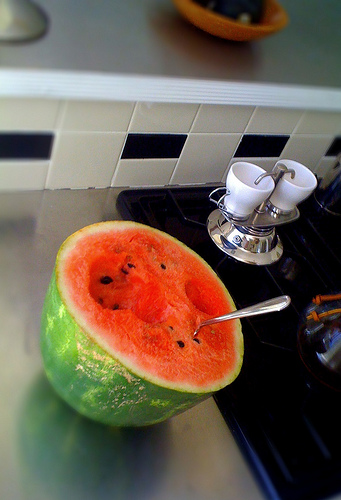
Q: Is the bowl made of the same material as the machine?
A: No, the bowl is made of wood and the machine is made of metal.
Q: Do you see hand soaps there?
A: No, there are no hand soaps.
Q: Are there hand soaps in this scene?
A: No, there are no hand soaps.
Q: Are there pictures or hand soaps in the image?
A: No, there are no hand soaps or pictures.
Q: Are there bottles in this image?
A: No, there are no bottles.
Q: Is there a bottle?
A: No, there are no bottles.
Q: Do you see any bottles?
A: No, there are no bottles.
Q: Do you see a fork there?
A: Yes, there is a fork.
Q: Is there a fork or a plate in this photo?
A: Yes, there is a fork.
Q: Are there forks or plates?
A: Yes, there is a fork.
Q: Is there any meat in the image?
A: No, there is no meat.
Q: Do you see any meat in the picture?
A: No, there is no meat.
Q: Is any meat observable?
A: No, there is no meat.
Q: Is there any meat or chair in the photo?
A: No, there are no meat or chairs.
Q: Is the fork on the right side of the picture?
A: Yes, the fork is on the right of the image.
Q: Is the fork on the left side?
A: No, the fork is on the right of the image.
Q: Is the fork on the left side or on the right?
A: The fork is on the right of the image.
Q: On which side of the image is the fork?
A: The fork is on the right of the image.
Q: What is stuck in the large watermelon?
A: The fork is stuck in the watermelon.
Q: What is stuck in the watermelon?
A: The fork is stuck in the watermelon.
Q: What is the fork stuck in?
A: The fork is stuck in the watermelon.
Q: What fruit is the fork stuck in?
A: The fork is stuck in the watermelon.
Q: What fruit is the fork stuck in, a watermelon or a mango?
A: The fork is stuck in a watermelon.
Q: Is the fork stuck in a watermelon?
A: Yes, the fork is stuck in a watermelon.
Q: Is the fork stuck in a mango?
A: No, the fork is stuck in a watermelon.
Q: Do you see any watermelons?
A: Yes, there is a watermelon.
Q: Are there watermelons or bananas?
A: Yes, there is a watermelon.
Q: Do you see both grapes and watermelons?
A: No, there is a watermelon but no grapes.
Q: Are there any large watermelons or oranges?
A: Yes, there is a large watermelon.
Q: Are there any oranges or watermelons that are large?
A: Yes, the watermelon is large.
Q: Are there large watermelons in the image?
A: Yes, there is a large watermelon.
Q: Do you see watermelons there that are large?
A: Yes, there is a watermelon that is large.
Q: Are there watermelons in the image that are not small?
A: Yes, there is a large watermelon.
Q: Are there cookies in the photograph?
A: No, there are no cookies.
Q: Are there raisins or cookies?
A: No, there are no cookies or raisins.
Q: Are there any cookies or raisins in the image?
A: No, there are no cookies or raisins.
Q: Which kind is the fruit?
A: The fruit is a watermelon.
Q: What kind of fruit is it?
A: The fruit is a watermelon.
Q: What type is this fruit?
A: This is a watermelon.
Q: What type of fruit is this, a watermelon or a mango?
A: This is a watermelon.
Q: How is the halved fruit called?
A: The fruit is a watermelon.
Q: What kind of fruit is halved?
A: The fruit is a watermelon.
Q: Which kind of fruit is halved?
A: The fruit is a watermelon.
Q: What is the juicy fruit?
A: The fruit is a watermelon.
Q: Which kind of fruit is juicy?
A: The fruit is a watermelon.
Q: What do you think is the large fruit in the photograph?
A: The fruit is a watermelon.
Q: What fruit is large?
A: The fruit is a watermelon.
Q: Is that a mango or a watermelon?
A: That is a watermelon.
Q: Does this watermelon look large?
A: Yes, the watermelon is large.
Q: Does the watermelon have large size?
A: Yes, the watermelon is large.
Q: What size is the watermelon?
A: The watermelon is large.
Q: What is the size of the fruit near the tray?
A: The watermelon is large.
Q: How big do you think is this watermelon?
A: The watermelon is large.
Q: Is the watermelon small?
A: No, the watermelon is large.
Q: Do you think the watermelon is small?
A: No, the watermelon is large.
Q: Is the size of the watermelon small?
A: No, the watermelon is large.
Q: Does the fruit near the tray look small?
A: No, the watermelon is large.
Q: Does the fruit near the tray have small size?
A: No, the watermelon is large.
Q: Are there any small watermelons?
A: No, there is a watermelon but it is large.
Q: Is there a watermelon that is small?
A: No, there is a watermelon but it is large.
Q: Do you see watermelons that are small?
A: No, there is a watermelon but it is large.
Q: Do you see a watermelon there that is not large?
A: No, there is a watermelon but it is large.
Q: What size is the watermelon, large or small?
A: The watermelon is large.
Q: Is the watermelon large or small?
A: The watermelon is large.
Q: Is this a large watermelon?
A: Yes, this is a large watermelon.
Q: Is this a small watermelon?
A: No, this is a large watermelon.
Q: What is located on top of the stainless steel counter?
A: The watermelon is on top of the counter.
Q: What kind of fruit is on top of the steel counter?
A: The fruit is a watermelon.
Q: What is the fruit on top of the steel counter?
A: The fruit is a watermelon.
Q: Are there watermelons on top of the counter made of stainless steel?
A: Yes, there is a watermelon on top of the counter.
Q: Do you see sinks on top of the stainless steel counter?
A: No, there is a watermelon on top of the counter.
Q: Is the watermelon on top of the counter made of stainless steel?
A: Yes, the watermelon is on top of the counter.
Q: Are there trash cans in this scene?
A: No, there are no trash cans.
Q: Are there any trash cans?
A: No, there are no trash cans.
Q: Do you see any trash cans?
A: No, there are no trash cans.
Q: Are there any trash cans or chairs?
A: No, there are no trash cans or chairs.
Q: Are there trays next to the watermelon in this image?
A: Yes, there is a tray next to the watermelon.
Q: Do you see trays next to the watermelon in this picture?
A: Yes, there is a tray next to the watermelon.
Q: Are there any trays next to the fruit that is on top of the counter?
A: Yes, there is a tray next to the watermelon.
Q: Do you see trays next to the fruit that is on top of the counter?
A: Yes, there is a tray next to the watermelon.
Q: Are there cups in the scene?
A: Yes, there is a cup.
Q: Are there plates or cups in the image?
A: Yes, there is a cup.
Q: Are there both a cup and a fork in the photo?
A: Yes, there are both a cup and a fork.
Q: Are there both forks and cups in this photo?
A: Yes, there are both a cup and a fork.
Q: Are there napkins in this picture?
A: No, there are no napkins.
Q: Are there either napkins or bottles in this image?
A: No, there are no napkins or bottles.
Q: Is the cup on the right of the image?
A: Yes, the cup is on the right of the image.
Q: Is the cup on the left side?
A: No, the cup is on the right of the image.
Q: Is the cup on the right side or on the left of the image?
A: The cup is on the right of the image.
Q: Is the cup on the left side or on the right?
A: The cup is on the right of the image.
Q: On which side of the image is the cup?
A: The cup is on the right of the image.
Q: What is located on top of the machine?
A: The cup is on top of the machine.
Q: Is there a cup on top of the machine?
A: Yes, there is a cup on top of the machine.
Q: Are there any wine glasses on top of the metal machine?
A: No, there is a cup on top of the machine.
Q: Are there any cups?
A: Yes, there is a cup.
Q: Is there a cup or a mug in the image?
A: Yes, there is a cup.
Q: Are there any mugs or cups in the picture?
A: Yes, there is a cup.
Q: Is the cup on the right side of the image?
A: Yes, the cup is on the right of the image.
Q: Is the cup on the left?
A: No, the cup is on the right of the image.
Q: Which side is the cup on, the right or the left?
A: The cup is on the right of the image.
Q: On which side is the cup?
A: The cup is on the right of the image.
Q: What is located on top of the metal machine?
A: The cup is on top of the machine.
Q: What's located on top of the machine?
A: The cup is on top of the machine.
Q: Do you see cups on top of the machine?
A: Yes, there is a cup on top of the machine.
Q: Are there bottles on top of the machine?
A: No, there is a cup on top of the machine.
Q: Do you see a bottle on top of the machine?
A: No, there is a cup on top of the machine.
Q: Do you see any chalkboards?
A: No, there are no chalkboards.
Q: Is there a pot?
A: No, there are no pots.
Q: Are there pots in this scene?
A: No, there are no pots.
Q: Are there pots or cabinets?
A: No, there are no pots or cabinets.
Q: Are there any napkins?
A: No, there are no napkins.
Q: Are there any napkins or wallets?
A: No, there are no napkins or wallets.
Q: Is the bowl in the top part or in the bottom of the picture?
A: The bowl is in the top of the image.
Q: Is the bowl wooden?
A: Yes, the bowl is wooden.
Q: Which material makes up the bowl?
A: The bowl is made of wood.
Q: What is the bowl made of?
A: The bowl is made of wood.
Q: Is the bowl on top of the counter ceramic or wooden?
A: The bowl is wooden.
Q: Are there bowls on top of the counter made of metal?
A: Yes, there is a bowl on top of the counter.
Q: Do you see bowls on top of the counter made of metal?
A: Yes, there is a bowl on top of the counter.